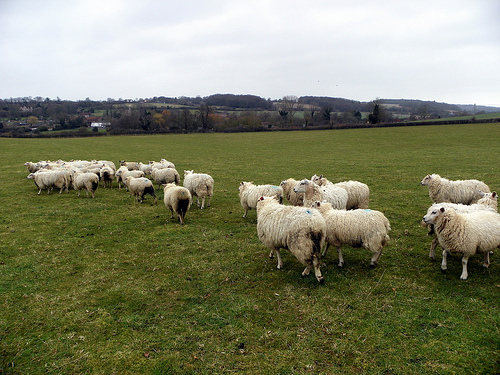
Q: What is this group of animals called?
A: Herd.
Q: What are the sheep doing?
A: Walking.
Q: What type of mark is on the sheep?
A: Blue.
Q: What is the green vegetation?
A: Grass.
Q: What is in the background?
A: Hills.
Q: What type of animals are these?
A: Sheep.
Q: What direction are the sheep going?
A: Away from the camera.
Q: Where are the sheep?
A: In a green field.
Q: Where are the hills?
A: Behind the sheep.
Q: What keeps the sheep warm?
A: Wool.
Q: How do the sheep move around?
A: Walking.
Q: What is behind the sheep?
A: Rolling hills.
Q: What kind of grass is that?
A: It is green grass.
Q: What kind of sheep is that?
A: It is a white sheep.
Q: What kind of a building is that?
A: The building is white.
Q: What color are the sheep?
A: White.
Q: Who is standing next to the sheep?
A: No one.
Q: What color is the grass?
A: Green.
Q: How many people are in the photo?
A: Zero.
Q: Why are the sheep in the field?
A: Grazing.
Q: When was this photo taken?
A: Daytime.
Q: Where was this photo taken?
A: In a field.